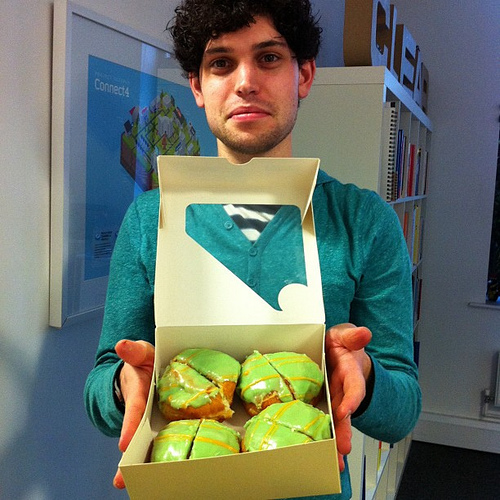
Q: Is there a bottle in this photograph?
A: No, there are no bottles.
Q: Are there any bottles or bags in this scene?
A: No, there are no bottles or bags.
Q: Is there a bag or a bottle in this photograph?
A: No, there are no bottles or bags.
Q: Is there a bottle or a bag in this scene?
A: No, there are no bottles or bags.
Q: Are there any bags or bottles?
A: No, there are no bottles or bags.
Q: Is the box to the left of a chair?
A: No, the box is to the left of a book.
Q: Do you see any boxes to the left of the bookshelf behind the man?
A: Yes, there is a box to the left of the bookshelf.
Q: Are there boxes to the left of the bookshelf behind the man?
A: Yes, there is a box to the left of the bookshelf.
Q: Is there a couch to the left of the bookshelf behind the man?
A: No, there is a box to the left of the bookshelf.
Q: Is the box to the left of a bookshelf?
A: Yes, the box is to the left of a bookshelf.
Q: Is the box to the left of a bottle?
A: No, the box is to the left of a bookshelf.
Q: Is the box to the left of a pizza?
A: No, the box is to the left of a book.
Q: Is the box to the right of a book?
A: No, the box is to the left of a book.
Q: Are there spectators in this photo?
A: No, there are no spectators.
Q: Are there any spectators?
A: No, there are no spectators.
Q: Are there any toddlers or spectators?
A: No, there are no spectators or toddlers.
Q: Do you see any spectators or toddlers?
A: No, there are no spectators or toddlers.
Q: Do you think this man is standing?
A: Yes, the man is standing.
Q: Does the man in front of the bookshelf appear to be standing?
A: Yes, the man is standing.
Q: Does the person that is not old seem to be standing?
A: Yes, the man is standing.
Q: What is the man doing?
A: The man is standing.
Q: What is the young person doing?
A: The man is standing.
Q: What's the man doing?
A: The man is standing.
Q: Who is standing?
A: The man is standing.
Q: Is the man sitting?
A: No, the man is standing.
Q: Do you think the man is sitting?
A: No, the man is standing.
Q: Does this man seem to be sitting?
A: No, the man is standing.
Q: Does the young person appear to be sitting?
A: No, the man is standing.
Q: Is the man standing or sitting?
A: The man is standing.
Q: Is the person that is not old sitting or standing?
A: The man is standing.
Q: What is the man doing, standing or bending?
A: The man is standing.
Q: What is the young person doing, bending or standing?
A: The man is standing.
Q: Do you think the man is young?
A: Yes, the man is young.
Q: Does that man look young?
A: Yes, the man is young.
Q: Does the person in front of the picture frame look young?
A: Yes, the man is young.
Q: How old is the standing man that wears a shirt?
A: The man is young.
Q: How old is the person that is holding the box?
A: The man is young.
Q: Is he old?
A: No, the man is young.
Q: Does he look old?
A: No, the man is young.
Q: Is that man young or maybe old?
A: The man is young.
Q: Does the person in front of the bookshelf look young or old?
A: The man is young.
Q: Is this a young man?
A: Yes, this is a young man.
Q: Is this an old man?
A: No, this is a young man.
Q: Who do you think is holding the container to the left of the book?
A: The man is holding the box.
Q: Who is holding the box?
A: The man is holding the box.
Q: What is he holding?
A: The man is holding the box.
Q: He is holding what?
A: The man is holding the box.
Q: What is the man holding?
A: The man is holding the box.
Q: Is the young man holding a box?
A: Yes, the man is holding a box.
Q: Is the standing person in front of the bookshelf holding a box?
A: Yes, the man is holding a box.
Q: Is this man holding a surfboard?
A: No, the man is holding a box.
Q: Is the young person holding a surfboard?
A: No, the man is holding a box.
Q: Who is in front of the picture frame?
A: The man is in front of the picture frame.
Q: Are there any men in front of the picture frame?
A: Yes, there is a man in front of the picture frame.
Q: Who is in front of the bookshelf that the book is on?
A: The man is in front of the bookshelf.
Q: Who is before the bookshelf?
A: The man is in front of the bookshelf.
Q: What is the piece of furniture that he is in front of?
A: The piece of furniture is a bookshelf.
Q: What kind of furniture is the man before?
A: The man is in front of the bookshelf.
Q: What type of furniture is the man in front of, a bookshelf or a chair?
A: The man is in front of a bookshelf.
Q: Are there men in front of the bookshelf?
A: Yes, there is a man in front of the bookshelf.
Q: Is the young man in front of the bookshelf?
A: Yes, the man is in front of the bookshelf.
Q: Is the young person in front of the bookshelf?
A: Yes, the man is in front of the bookshelf.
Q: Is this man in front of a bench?
A: No, the man is in front of the bookshelf.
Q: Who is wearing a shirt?
A: The man is wearing a shirt.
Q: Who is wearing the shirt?
A: The man is wearing a shirt.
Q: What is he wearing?
A: The man is wearing a shirt.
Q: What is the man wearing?
A: The man is wearing a shirt.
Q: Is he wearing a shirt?
A: Yes, the man is wearing a shirt.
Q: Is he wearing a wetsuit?
A: No, the man is wearing a shirt.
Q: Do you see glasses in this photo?
A: No, there are no glasses.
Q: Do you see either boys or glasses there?
A: No, there are no glasses or boys.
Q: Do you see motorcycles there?
A: No, there are no motorcycles.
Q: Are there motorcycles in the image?
A: No, there are no motorcycles.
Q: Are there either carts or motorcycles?
A: No, there are no motorcycles or carts.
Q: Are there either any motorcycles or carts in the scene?
A: No, there are no motorcycles or carts.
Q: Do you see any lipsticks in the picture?
A: No, there are no lipsticks.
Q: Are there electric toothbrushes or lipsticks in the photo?
A: No, there are no lipsticks or electric toothbrushes.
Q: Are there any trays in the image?
A: No, there are no trays.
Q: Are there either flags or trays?
A: No, there are no trays or flags.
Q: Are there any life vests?
A: No, there are no life vests.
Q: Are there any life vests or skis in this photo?
A: No, there are no life vests or skis.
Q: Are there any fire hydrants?
A: No, there are no fire hydrants.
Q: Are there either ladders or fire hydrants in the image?
A: No, there are no fire hydrants or ladders.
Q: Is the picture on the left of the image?
A: Yes, the picture is on the left of the image.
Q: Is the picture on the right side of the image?
A: No, the picture is on the left of the image.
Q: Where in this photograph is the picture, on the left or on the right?
A: The picture is on the left of the image.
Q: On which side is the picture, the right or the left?
A: The picture is on the left of the image.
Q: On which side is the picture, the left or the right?
A: The picture is on the left of the image.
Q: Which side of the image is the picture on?
A: The picture is on the left of the image.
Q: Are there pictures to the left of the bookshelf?
A: Yes, there is a picture to the left of the bookshelf.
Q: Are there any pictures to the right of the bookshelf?
A: No, the picture is to the left of the bookshelf.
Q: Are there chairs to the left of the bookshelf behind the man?
A: No, there is a picture to the left of the bookshelf.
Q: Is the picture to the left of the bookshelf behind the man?
A: Yes, the picture is to the left of the bookshelf.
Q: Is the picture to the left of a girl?
A: No, the picture is to the left of the bookshelf.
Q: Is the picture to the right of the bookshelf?
A: No, the picture is to the left of the bookshelf.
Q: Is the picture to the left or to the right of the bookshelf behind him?
A: The picture is to the left of the bookshelf.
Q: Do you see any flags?
A: No, there are no flags.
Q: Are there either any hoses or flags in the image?
A: No, there are no flags or hoses.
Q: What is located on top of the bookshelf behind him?
A: The letter is on top of the bookshelf.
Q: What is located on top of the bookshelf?
A: The letter is on top of the bookshelf.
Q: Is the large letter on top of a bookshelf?
A: Yes, the letter is on top of a bookshelf.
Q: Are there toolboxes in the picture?
A: No, there are no toolboxes.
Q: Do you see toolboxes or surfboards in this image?
A: No, there are no toolboxes or surfboards.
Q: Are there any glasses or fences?
A: No, there are no glasses or fences.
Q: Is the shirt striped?
A: Yes, the shirt is striped.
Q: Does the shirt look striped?
A: Yes, the shirt is striped.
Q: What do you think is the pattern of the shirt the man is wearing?
A: The shirt is striped.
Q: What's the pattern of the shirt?
A: The shirt is striped.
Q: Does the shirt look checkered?
A: No, the shirt is striped.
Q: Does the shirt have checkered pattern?
A: No, the shirt is striped.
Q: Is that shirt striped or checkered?
A: The shirt is striped.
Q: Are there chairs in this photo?
A: No, there are no chairs.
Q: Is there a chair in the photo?
A: No, there are no chairs.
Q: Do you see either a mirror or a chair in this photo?
A: No, there are no chairs or mirrors.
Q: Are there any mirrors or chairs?
A: No, there are no chairs or mirrors.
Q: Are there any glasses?
A: No, there are no glasses.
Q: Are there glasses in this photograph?
A: No, there are no glasses.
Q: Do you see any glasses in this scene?
A: No, there are no glasses.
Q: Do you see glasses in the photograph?
A: No, there are no glasses.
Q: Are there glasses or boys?
A: No, there are no glasses or boys.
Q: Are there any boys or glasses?
A: No, there are no glasses or boys.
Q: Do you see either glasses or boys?
A: No, there are no glasses or boys.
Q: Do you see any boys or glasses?
A: No, there are no glasses or boys.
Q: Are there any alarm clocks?
A: No, there are no alarm clocks.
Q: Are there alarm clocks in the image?
A: No, there are no alarm clocks.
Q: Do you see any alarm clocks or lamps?
A: No, there are no alarm clocks or lamps.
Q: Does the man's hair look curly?
A: Yes, the hair is curly.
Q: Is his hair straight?
A: No, the hair is curly.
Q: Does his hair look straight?
A: No, the hair is curly.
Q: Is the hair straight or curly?
A: The hair is curly.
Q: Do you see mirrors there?
A: No, there are no mirrors.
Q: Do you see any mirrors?
A: No, there are no mirrors.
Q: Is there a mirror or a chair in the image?
A: No, there are no mirrors or chairs.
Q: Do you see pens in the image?
A: No, there are no pens.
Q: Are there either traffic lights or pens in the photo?
A: No, there are no pens or traffic lights.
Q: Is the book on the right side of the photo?
A: Yes, the book is on the right of the image.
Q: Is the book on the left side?
A: No, the book is on the right of the image.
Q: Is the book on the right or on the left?
A: The book is on the right of the image.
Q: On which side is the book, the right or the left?
A: The book is on the right of the image.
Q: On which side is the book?
A: The book is on the right of the image.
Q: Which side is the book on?
A: The book is on the right of the image.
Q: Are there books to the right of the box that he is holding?
A: Yes, there is a book to the right of the box.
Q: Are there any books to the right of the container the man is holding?
A: Yes, there is a book to the right of the box.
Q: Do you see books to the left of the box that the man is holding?
A: No, the book is to the right of the box.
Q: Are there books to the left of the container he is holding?
A: No, the book is to the right of the box.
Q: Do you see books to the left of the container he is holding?
A: No, the book is to the right of the box.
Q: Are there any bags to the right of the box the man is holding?
A: No, there is a book to the right of the box.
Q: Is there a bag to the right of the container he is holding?
A: No, there is a book to the right of the box.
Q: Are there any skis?
A: No, there are no skis.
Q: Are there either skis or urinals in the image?
A: No, there are no skis or urinals.